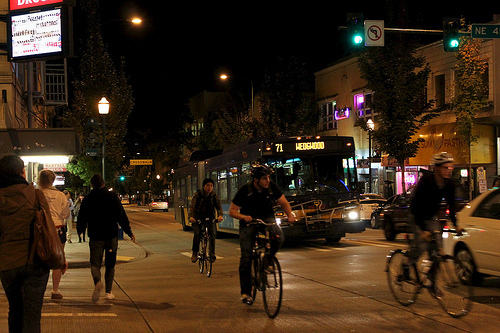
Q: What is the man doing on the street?
A: Riding his bike.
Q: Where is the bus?
A: On the street.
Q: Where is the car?
A: Driving on the street.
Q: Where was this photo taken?
A: On a street.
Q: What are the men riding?
A: Bicycles.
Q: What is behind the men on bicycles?
A: A bus.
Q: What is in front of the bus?
A: A white car.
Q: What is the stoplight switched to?
A: Green.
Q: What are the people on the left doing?
A: Crossing the street.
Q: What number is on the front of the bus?
A: 71.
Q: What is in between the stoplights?
A: A white sign.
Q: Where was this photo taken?
A: In a city.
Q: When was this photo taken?
A: At nighttime.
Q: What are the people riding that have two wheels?
A: Bicycles.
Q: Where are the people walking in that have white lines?
A: Crosswalk.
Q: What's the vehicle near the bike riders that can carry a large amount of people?
A: Bus.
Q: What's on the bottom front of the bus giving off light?
A: Headlights.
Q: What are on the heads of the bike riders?
A: Helmets.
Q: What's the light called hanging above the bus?
A: Traffic light.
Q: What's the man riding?
A: A bike.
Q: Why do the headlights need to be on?
A: It's nighttime.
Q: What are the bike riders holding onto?
A: Handlebars.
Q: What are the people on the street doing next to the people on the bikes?
A: Walking.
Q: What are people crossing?
A: Street.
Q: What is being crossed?
A: Street.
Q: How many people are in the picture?
A: Six.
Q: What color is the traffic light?
A: Green.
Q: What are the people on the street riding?
A: Bicycles.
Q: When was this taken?
A: Night.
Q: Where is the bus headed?
A: Wedgewood.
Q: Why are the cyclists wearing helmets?
A: For safety.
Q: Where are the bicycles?
A: On the street.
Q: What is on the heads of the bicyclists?
A: Helmets.